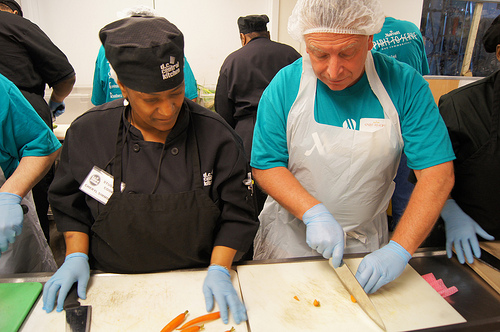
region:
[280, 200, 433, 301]
cook has blue gloves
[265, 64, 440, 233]
cook has teal shirt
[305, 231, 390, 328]
cook is holding knife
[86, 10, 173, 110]
woman has black hat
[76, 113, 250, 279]
woman has black apron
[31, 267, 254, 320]
woman has blue gloves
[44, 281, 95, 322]
black handled knife on board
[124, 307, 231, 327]
orange carrots on board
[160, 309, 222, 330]
some carrots on the cutting board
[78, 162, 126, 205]
the nametag attached to the apron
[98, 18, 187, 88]
the black hat on the man's head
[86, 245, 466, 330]
the cutting boards on the table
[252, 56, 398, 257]
the the apron the man is wearing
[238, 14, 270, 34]
the hat on the man's head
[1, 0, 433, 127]
some chefs working at another counter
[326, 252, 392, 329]
the knife in the man's hand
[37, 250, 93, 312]
the rubber glove on the woman's hand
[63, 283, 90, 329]
the knife sitting on the table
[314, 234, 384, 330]
Man holding a knife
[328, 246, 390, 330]
Man holding a chef's knife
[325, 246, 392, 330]
Man is holding a chef's knife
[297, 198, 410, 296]
Man is wearing gloves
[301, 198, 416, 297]
Man wearing blue gloves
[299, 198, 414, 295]
Man is wearing blue gloves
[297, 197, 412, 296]
Man wearing rubber gloves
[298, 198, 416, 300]
Man is wearing rubber gloves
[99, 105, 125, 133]
black fabric on shirt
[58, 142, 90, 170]
black fabric on shirt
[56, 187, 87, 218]
black fabric on shirt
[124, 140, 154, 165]
black fabric on shirt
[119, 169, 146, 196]
black fabric on shirt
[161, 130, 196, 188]
black fabric on shirt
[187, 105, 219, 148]
black fabric on shirt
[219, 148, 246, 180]
black fabric on shirt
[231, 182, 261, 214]
black fabric on shirt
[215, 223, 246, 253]
black fabric on shirt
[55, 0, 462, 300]
Two chefs slicing carrots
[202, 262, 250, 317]
A thin blue glove on the woman's hand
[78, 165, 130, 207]
A white tag on the woman's black shirt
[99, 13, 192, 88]
A black chef's hat on the woman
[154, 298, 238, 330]
A number of long orange carrots by the woman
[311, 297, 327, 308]
A thin orange slice of carrot on the white paper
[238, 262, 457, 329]
A sheet of white paper beneath the knife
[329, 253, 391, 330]
A large chef's knife in the man's hand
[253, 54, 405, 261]
A white apron on the man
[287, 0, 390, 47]
A white plastic cap on the man's head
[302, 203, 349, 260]
a disposable blue glove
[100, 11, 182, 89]
a black and white chef hat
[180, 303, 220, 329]
a long orange carrot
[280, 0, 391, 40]
a white hair net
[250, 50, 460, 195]
a blue and white short sleeve shirt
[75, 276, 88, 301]
blue finger on glove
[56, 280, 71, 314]
blue finger on glove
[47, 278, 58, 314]
blue finger on glove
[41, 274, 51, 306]
blue finger on glove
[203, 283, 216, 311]
blue finger on glove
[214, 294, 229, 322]
blue finger on glove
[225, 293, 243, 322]
blue finger on glove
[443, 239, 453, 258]
blue finger on glove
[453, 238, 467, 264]
blue finger on glove